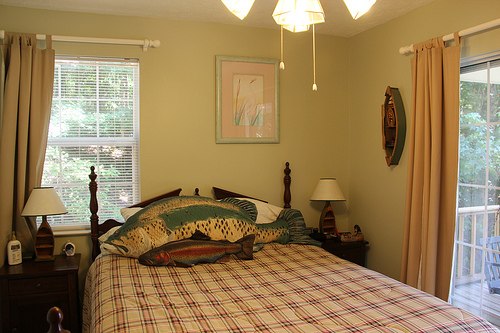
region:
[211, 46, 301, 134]
image on the wall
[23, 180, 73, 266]
lamp on the desk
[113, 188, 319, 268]
stuffed toys on the bed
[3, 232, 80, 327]
desk with drawers in it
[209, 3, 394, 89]
lights on the ceiling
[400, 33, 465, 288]
curtain to the window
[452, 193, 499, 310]
deck outside the window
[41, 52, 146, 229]
window with blinds open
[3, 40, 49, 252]
curtain on the window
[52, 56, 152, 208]
white mini blinds on window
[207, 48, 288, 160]
picture with white frame on the wall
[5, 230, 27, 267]
bottle on lotion on nightstand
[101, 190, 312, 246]
bog green and white fish on the bed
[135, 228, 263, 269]
brown fish on the bed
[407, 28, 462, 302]
tan curtains for sliding glass window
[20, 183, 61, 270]
brown lamp on nightstand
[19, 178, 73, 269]
white lampshade on lamp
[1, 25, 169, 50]
white curtain rod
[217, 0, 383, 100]
a light fixture is hanging from the ceiling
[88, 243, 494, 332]
the bed has a plaid spread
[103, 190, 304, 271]
fish pillows are on the bed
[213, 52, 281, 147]
a framed picture is on the wall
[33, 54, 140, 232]
the window has white open shades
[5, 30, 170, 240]
a white curtain rod is above the window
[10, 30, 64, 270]
beige curtains are hanging from the rod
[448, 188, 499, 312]
a wooden balcony is off the bedroom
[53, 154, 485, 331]
the bedstead is a four poster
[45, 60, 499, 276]
woods surround the room outside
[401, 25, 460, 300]
tan tab top curtains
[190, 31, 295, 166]
framed picture on a wall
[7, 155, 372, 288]
matching lamps on bedside stands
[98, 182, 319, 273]
two pillows shaped like fish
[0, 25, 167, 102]
white curtain rod above window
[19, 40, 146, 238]
window with venetian blinds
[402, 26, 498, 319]
sliding glass door leading to deck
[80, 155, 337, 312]
two fish pillows on a bed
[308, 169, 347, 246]
lamp with a white shade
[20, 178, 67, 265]
lamp with base shaped like rowboat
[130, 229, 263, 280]
pillow of a fish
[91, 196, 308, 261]
bigger pillow of a fish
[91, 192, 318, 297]
pillows on a bed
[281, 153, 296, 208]
post of the bed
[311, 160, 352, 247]
lamp by the bed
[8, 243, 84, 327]
table next to the bed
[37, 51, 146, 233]
blinds in the window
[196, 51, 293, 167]
picture on the wall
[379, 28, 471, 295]
curtains in the doorway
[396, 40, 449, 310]
plets in the curtains